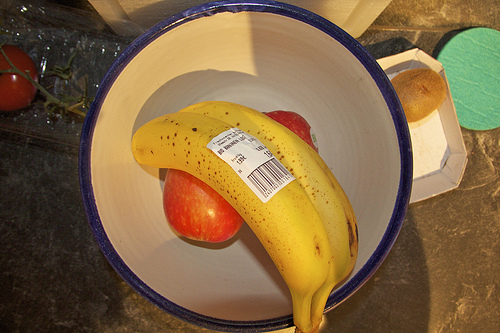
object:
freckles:
[188, 127, 200, 135]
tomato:
[0, 43, 39, 114]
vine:
[1, 46, 91, 116]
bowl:
[75, 1, 413, 330]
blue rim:
[381, 85, 413, 294]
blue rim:
[76, 79, 110, 252]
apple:
[163, 168, 245, 244]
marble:
[0, 0, 498, 332]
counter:
[2, 2, 498, 329]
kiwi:
[389, 70, 446, 121]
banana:
[130, 110, 331, 331]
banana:
[180, 100, 357, 332]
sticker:
[206, 126, 295, 202]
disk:
[435, 25, 499, 132]